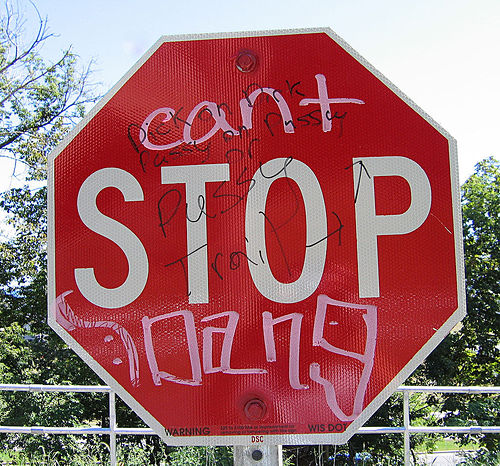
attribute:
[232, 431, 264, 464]
pole — metal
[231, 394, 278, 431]
bolt — red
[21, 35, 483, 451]
sign — stop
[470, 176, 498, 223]
trees — Green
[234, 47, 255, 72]
bolt — metal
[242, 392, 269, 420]
bolt — metal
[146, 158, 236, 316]
letter t — white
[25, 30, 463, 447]
stop sign — red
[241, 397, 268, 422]
bolt — red painted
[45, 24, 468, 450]
sign — red, reflective, stop, red and white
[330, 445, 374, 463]
flowers — blue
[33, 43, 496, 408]
stop sign — red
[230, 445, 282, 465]
pole — metal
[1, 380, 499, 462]
fence — metal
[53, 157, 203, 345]
letter — S, large, white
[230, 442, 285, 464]
pole — grey